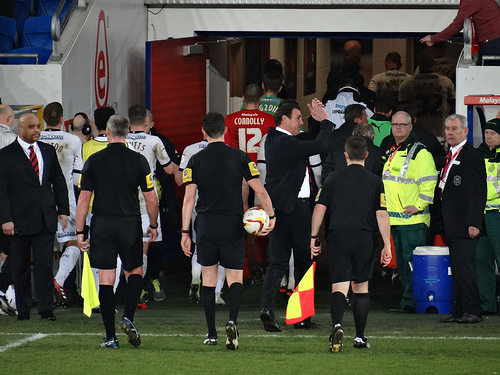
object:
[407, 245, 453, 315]
cooler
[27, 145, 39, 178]
tie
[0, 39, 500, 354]
crowd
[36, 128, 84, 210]
shirt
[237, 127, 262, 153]
number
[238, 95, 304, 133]
uniform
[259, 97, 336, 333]
man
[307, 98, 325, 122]
hand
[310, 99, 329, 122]
hand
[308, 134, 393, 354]
man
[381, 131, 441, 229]
jacket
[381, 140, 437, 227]
shirt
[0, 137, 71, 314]
suit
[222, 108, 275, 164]
red jersey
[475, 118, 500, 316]
man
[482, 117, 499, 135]
toboggan hat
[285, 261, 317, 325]
flag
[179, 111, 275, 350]
guy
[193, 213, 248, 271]
shorts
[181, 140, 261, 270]
soccer uniform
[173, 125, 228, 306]
man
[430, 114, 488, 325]
man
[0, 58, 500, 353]
players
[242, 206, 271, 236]
ball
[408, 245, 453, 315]
water jug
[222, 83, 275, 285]
man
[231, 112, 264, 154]
white lettering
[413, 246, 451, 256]
lid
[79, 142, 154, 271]
uniform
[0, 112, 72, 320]
bald guy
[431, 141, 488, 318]
suit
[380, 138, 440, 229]
top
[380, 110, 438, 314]
guy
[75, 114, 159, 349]
man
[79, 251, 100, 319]
cloth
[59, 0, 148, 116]
tunnel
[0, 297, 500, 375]
field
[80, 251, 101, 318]
towel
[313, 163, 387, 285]
uniform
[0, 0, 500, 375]
game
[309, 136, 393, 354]
boy